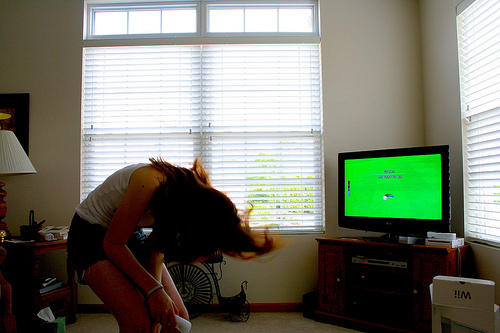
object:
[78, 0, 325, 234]
window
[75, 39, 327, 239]
blinds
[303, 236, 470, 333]
stand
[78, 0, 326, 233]
blinds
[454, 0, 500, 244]
blinds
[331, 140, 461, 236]
flip flop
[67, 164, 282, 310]
girl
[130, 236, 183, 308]
bracelet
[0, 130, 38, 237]
lamp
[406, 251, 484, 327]
box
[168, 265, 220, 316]
fan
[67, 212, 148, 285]
shorts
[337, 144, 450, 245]
television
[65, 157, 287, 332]
girl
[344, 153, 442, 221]
screen